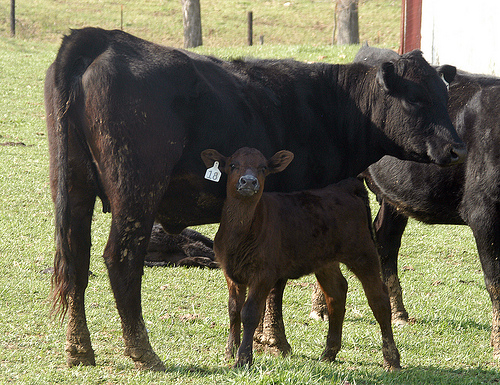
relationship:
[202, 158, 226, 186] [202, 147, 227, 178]
tag on ear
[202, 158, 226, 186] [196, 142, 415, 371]
tag on calf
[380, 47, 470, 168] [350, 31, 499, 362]
face against body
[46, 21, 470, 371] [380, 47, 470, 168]
cow has face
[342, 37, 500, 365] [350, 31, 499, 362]
cow has body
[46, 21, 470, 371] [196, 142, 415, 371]
cow behind calf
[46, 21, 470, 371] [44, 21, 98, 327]
cow has tail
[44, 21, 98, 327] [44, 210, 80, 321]
tail with strands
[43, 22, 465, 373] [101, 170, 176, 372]
animal has leg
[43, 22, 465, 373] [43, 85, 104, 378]
animal has leg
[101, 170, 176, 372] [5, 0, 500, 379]
leg on grass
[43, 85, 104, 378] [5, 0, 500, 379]
leg on grass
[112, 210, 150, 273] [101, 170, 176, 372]
dents on leg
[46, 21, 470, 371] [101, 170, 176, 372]
cow has leg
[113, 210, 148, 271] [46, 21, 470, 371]
nicks on cow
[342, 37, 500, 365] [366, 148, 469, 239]
animal has underside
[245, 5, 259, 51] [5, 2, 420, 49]
post on fence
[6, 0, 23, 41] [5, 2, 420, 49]
post on fence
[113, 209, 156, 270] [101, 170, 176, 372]
knobs on leg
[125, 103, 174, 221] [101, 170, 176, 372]
protrusions on leg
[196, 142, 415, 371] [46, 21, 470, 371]
calf next to cow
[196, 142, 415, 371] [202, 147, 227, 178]
calf has ear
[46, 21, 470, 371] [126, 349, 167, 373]
cow has hoof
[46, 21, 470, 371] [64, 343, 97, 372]
cow has hoof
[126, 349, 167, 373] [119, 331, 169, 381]
hoof covered in mud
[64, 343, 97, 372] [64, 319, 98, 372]
hoof covered in mud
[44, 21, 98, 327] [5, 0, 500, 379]
tail almost touching ground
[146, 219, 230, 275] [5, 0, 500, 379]
cow laying on ground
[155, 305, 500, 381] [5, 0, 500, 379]
shadow on ground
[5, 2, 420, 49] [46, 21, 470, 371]
fence around cow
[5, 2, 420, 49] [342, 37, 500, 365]
fence around cow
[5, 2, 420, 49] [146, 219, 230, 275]
fence around cow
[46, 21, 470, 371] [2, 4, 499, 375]
cow standing in pasture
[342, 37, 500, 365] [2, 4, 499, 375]
cow standing in pasture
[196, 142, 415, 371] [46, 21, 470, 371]
calf next to mother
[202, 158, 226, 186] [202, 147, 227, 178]
tag in ear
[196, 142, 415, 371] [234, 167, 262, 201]
calf has nose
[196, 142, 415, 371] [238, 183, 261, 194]
calf has mouth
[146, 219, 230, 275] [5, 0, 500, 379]
cow on ground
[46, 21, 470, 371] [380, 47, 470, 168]
cow has head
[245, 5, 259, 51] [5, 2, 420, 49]
post nailed to fence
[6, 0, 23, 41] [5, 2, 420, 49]
post nailed to fence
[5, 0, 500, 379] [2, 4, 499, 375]
grass in pasture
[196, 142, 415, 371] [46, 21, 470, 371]
calf under cow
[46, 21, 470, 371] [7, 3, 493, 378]
cow in field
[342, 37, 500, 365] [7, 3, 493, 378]
cow in field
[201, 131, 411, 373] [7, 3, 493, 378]
cow in field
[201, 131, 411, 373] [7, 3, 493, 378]
cow standing in field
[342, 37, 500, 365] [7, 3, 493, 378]
cow standing in field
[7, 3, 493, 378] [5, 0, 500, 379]
field with grass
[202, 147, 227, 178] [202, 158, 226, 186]
ear with tag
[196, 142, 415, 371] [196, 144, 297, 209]
calf has head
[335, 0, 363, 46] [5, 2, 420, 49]
trunk near fence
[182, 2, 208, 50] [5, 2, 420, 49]
trunk near fence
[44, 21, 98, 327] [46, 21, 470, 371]
tail on cow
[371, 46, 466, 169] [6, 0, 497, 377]
head obstructing view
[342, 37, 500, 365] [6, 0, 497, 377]
cow has view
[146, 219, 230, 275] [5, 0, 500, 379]
cow reclining on grass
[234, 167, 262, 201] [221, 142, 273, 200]
nose on face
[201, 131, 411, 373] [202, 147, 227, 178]
cow has ear